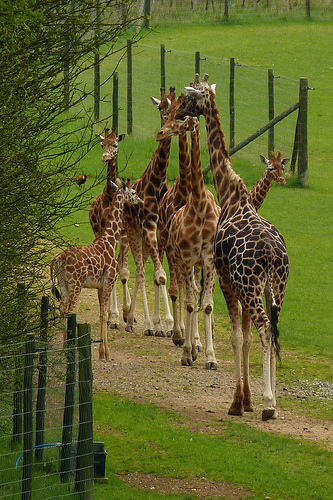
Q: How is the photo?
A: Clear.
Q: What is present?
A: Animals.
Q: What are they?
A: Girraffes.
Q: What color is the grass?
A: Green.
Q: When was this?
A: Daytime.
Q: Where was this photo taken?
A: At zoo.